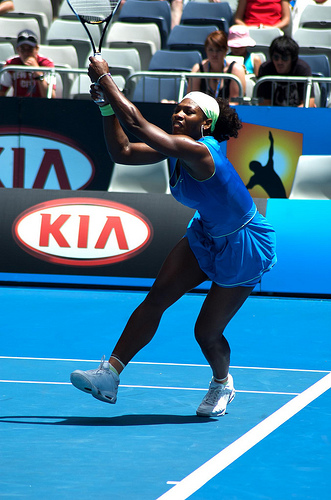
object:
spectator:
[186, 28, 247, 106]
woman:
[68, 48, 279, 420]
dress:
[167, 135, 278, 290]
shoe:
[70, 354, 121, 404]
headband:
[178, 90, 221, 134]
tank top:
[166, 133, 257, 239]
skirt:
[182, 201, 279, 290]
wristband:
[98, 103, 115, 117]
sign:
[10, 195, 154, 267]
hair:
[198, 89, 244, 144]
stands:
[103, 18, 162, 54]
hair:
[205, 30, 231, 53]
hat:
[15, 29, 38, 50]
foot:
[195, 372, 236, 417]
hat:
[226, 27, 257, 48]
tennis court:
[0, 285, 331, 500]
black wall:
[0, 185, 197, 280]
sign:
[225, 122, 304, 199]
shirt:
[0, 54, 56, 98]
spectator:
[0, 27, 57, 98]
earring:
[200, 124, 205, 138]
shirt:
[254, 58, 316, 108]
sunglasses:
[271, 53, 294, 63]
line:
[156, 371, 331, 500]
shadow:
[0, 412, 220, 426]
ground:
[0, 287, 330, 499]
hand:
[87, 53, 110, 85]